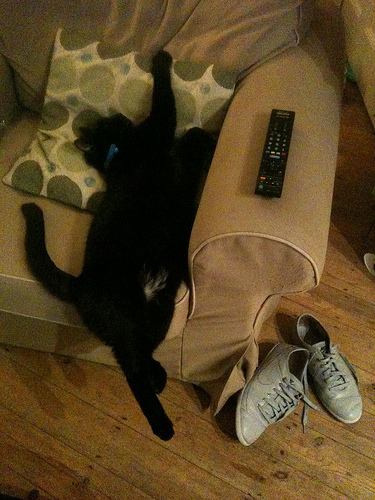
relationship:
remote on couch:
[252, 104, 299, 203] [1, 3, 351, 423]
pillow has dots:
[7, 22, 243, 214] [9, 25, 240, 213]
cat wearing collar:
[18, 39, 218, 453] [102, 141, 125, 166]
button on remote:
[259, 173, 268, 181] [252, 104, 299, 203]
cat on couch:
[18, 39, 218, 453] [1, 3, 351, 423]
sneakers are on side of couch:
[230, 311, 367, 451] [1, 3, 351, 423]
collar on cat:
[102, 141, 125, 166] [18, 39, 218, 453]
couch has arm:
[1, 3, 351, 423] [191, 6, 346, 314]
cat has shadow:
[18, 39, 218, 453] [4, 290, 107, 427]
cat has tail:
[18, 39, 218, 453] [17, 197, 81, 311]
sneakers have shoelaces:
[230, 311, 367, 451] [254, 347, 353, 432]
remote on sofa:
[252, 104, 299, 203] [1, 3, 351, 423]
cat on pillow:
[18, 39, 218, 453] [7, 22, 243, 214]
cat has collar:
[18, 39, 218, 453] [102, 141, 125, 166]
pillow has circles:
[7, 22, 243, 214] [9, 25, 240, 213]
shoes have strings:
[230, 311, 367, 451] [254, 347, 353, 432]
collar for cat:
[102, 141, 125, 166] [18, 39, 218, 453]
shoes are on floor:
[230, 311, 367, 451] [5, 352, 370, 500]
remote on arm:
[252, 104, 299, 203] [191, 6, 346, 314]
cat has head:
[18, 39, 218, 453] [69, 110, 142, 174]